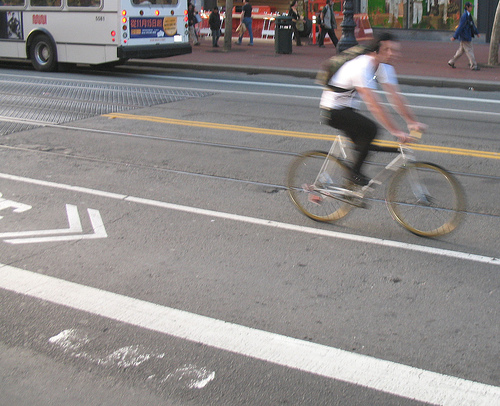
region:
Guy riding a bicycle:
[268, 40, 454, 256]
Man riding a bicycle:
[313, 40, 459, 248]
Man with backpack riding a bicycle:
[285, 30, 455, 230]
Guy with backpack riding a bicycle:
[277, 27, 469, 238]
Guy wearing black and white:
[306, 40, 451, 231]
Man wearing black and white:
[293, 45, 451, 246]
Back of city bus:
[2, 0, 199, 63]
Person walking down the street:
[420, 5, 496, 71]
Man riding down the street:
[256, 16, 491, 273]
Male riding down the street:
[246, 23, 476, 259]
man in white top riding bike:
[284, 29, 466, 239]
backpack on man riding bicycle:
[314, 30, 399, 96]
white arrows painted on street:
[3, 197, 117, 254]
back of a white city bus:
[117, 0, 194, 57]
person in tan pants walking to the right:
[447, 0, 483, 73]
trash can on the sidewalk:
[270, 14, 297, 55]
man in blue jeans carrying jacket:
[233, 0, 256, 48]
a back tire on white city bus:
[23, 27, 60, 74]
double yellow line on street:
[110, 109, 245, 135]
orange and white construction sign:
[355, 12, 375, 39]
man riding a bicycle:
[267, 26, 473, 256]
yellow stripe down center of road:
[97, 102, 497, 176]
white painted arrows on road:
[4, 194, 106, 254]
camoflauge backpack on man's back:
[308, 35, 373, 95]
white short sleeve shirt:
[318, 53, 399, 112]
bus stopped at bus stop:
[2, 2, 204, 68]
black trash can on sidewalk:
[270, 12, 298, 56]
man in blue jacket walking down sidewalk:
[445, 1, 480, 72]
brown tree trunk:
[217, 2, 238, 53]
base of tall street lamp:
[331, 2, 361, 57]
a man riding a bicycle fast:
[295, 30, 487, 297]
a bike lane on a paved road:
[23, 157, 291, 385]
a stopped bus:
[14, 4, 229, 94]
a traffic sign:
[357, 13, 379, 36]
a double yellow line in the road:
[117, 100, 238, 150]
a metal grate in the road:
[26, 79, 117, 131]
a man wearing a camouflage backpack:
[319, 22, 421, 145]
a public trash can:
[264, 11, 303, 61]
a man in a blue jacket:
[448, 5, 493, 74]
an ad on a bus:
[128, 15, 188, 44]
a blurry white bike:
[278, 120, 481, 255]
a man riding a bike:
[276, 23, 487, 258]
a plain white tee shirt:
[310, 44, 409, 124]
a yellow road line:
[85, 101, 498, 164]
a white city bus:
[2, 0, 209, 73]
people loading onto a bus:
[3, 2, 345, 72]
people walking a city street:
[199, 2, 499, 82]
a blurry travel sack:
[303, 38, 380, 96]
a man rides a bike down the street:
[6, 28, 491, 265]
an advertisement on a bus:
[117, 0, 197, 56]